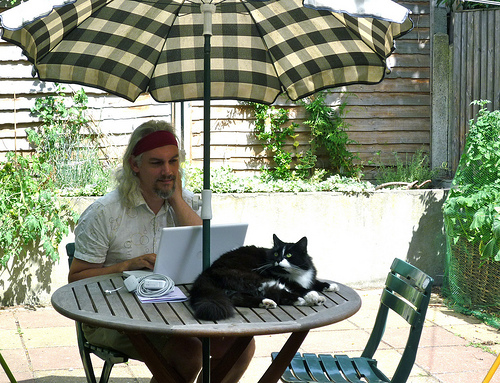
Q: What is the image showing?
A: It is showing a patio.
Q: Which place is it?
A: It is a patio.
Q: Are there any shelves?
A: No, there are no shelves.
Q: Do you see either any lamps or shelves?
A: No, there are no shelves or lamps.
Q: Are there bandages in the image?
A: No, there are no bandages.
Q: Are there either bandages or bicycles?
A: No, there are no bandages or bicycles.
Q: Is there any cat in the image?
A: Yes, there is a cat.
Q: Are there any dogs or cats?
A: Yes, there is a cat.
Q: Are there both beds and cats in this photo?
A: No, there is a cat but no beds.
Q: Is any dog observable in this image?
A: No, there are no dogs.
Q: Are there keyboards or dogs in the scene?
A: No, there are no dogs or keyboards.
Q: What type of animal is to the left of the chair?
A: The animal is a cat.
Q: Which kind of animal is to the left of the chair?
A: The animal is a cat.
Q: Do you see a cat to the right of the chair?
A: No, the cat is to the left of the chair.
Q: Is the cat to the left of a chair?
A: Yes, the cat is to the left of a chair.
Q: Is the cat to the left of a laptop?
A: No, the cat is to the left of a chair.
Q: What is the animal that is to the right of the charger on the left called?
A: The animal is a cat.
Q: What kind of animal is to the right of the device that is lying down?
A: The animal is a cat.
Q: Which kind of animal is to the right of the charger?
A: The animal is a cat.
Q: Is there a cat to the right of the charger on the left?
A: Yes, there is a cat to the right of the charger.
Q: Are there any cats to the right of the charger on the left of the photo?
A: Yes, there is a cat to the right of the charger.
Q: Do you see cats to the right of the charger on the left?
A: Yes, there is a cat to the right of the charger.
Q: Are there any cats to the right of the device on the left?
A: Yes, there is a cat to the right of the charger.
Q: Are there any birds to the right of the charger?
A: No, there is a cat to the right of the charger.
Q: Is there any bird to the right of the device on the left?
A: No, there is a cat to the right of the charger.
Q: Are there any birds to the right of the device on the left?
A: No, there is a cat to the right of the charger.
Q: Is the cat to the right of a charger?
A: Yes, the cat is to the right of a charger.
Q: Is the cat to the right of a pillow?
A: No, the cat is to the right of a charger.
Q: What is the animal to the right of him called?
A: The animal is a cat.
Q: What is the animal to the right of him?
A: The animal is a cat.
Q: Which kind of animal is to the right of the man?
A: The animal is a cat.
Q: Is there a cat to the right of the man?
A: Yes, there is a cat to the right of the man.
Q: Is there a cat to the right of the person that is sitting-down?
A: Yes, there is a cat to the right of the man.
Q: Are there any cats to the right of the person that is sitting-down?
A: Yes, there is a cat to the right of the man.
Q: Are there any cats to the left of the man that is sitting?
A: No, the cat is to the right of the man.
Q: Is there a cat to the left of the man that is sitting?
A: No, the cat is to the right of the man.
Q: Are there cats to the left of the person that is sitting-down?
A: No, the cat is to the right of the man.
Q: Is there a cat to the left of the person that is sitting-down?
A: No, the cat is to the right of the man.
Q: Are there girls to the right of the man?
A: No, there is a cat to the right of the man.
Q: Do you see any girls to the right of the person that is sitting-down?
A: No, there is a cat to the right of the man.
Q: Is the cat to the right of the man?
A: Yes, the cat is to the right of the man.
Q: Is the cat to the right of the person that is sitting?
A: Yes, the cat is to the right of the man.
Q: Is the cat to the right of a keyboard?
A: No, the cat is to the right of the man.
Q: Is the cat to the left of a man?
A: No, the cat is to the right of a man.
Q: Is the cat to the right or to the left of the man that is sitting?
A: The cat is to the right of the man.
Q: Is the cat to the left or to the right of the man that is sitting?
A: The cat is to the right of the man.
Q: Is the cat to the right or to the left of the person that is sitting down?
A: The cat is to the right of the man.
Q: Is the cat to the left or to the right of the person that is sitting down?
A: The cat is to the right of the man.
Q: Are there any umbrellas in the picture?
A: Yes, there is an umbrella.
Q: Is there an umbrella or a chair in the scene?
A: Yes, there is an umbrella.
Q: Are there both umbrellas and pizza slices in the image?
A: No, there is an umbrella but no pizza slices.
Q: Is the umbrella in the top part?
A: Yes, the umbrella is in the top of the image.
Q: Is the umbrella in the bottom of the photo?
A: No, the umbrella is in the top of the image.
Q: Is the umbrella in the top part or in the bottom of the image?
A: The umbrella is in the top of the image.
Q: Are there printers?
A: No, there are no printers.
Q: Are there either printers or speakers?
A: No, there are no printers or speakers.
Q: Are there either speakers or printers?
A: No, there are no printers or speakers.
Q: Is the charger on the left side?
A: Yes, the charger is on the left of the image.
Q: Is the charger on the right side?
A: No, the charger is on the left of the image.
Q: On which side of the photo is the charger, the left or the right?
A: The charger is on the left of the image.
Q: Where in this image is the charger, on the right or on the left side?
A: The charger is on the left of the image.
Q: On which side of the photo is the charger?
A: The charger is on the left of the image.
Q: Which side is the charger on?
A: The charger is on the left of the image.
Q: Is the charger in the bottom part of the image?
A: Yes, the charger is in the bottom of the image.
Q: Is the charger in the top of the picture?
A: No, the charger is in the bottom of the image.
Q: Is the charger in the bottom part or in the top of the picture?
A: The charger is in the bottom of the image.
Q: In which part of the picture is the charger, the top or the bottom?
A: The charger is in the bottom of the image.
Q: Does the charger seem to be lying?
A: Yes, the charger is lying.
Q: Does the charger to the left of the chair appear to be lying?
A: Yes, the charger is lying.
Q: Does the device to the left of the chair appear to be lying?
A: Yes, the charger is lying.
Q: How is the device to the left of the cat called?
A: The device is a charger.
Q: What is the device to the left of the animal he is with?
A: The device is a charger.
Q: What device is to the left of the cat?
A: The device is a charger.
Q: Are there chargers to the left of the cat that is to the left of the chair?
A: Yes, there is a charger to the left of the cat.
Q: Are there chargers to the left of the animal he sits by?
A: Yes, there is a charger to the left of the cat.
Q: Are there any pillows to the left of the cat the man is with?
A: No, there is a charger to the left of the cat.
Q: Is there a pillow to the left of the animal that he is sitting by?
A: No, there is a charger to the left of the cat.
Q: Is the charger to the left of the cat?
A: Yes, the charger is to the left of the cat.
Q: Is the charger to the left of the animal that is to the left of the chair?
A: Yes, the charger is to the left of the cat.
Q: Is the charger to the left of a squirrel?
A: No, the charger is to the left of the cat.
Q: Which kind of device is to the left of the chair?
A: The device is a charger.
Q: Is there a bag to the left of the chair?
A: No, there is a charger to the left of the chair.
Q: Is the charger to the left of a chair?
A: Yes, the charger is to the left of a chair.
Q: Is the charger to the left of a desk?
A: No, the charger is to the left of a chair.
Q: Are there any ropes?
A: No, there are no ropes.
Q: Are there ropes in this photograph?
A: No, there are no ropes.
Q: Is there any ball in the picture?
A: No, there are no balls.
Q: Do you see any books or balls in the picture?
A: No, there are no balls or books.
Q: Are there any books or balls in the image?
A: No, there are no balls or books.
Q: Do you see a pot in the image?
A: No, there are no pots.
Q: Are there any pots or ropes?
A: No, there are no pots or ropes.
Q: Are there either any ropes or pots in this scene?
A: No, there are no pots or ropes.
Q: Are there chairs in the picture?
A: Yes, there is a chair.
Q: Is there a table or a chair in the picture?
A: Yes, there is a chair.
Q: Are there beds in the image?
A: No, there are no beds.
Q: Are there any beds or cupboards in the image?
A: No, there are no beds or cupboards.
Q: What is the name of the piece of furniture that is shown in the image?
A: The piece of furniture is a chair.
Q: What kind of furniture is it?
A: The piece of furniture is a chair.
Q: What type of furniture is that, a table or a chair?
A: This is a chair.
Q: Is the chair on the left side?
A: No, the chair is on the right of the image.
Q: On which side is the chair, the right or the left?
A: The chair is on the right of the image.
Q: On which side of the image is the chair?
A: The chair is on the right of the image.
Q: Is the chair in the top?
A: No, the chair is in the bottom of the image.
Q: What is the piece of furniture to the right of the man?
A: The piece of furniture is a chair.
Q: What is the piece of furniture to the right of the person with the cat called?
A: The piece of furniture is a chair.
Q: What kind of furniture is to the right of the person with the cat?
A: The piece of furniture is a chair.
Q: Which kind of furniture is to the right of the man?
A: The piece of furniture is a chair.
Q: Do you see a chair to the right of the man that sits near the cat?
A: Yes, there is a chair to the right of the man.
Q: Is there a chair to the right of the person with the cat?
A: Yes, there is a chair to the right of the man.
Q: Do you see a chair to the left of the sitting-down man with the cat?
A: No, the chair is to the right of the man.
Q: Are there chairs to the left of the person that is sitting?
A: No, the chair is to the right of the man.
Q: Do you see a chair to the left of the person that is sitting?
A: No, the chair is to the right of the man.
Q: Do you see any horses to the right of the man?
A: No, there is a chair to the right of the man.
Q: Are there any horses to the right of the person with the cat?
A: No, there is a chair to the right of the man.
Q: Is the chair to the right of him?
A: Yes, the chair is to the right of the man.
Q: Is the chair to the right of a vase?
A: No, the chair is to the right of the man.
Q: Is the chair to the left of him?
A: No, the chair is to the right of a man.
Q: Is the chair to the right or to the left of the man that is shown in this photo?
A: The chair is to the right of the man.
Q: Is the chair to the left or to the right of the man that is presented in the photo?
A: The chair is to the right of the man.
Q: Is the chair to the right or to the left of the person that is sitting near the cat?
A: The chair is to the right of the man.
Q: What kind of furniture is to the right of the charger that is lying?
A: The piece of furniture is a chair.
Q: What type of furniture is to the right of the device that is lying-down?
A: The piece of furniture is a chair.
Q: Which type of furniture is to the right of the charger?
A: The piece of furniture is a chair.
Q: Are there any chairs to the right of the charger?
A: Yes, there is a chair to the right of the charger.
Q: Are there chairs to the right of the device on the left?
A: Yes, there is a chair to the right of the charger.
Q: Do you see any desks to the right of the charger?
A: No, there is a chair to the right of the charger.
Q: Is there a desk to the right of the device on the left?
A: No, there is a chair to the right of the charger.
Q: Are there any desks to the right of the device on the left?
A: No, there is a chair to the right of the charger.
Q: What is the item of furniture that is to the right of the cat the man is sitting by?
A: The piece of furniture is a chair.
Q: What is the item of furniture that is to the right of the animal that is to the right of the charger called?
A: The piece of furniture is a chair.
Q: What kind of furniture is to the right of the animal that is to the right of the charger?
A: The piece of furniture is a chair.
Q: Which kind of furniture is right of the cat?
A: The piece of furniture is a chair.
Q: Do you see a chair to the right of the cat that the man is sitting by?
A: Yes, there is a chair to the right of the cat.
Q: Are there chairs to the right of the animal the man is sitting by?
A: Yes, there is a chair to the right of the cat.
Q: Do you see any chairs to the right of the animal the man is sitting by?
A: Yes, there is a chair to the right of the cat.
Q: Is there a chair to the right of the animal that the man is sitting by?
A: Yes, there is a chair to the right of the cat.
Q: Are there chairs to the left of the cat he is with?
A: No, the chair is to the right of the cat.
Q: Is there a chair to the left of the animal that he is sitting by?
A: No, the chair is to the right of the cat.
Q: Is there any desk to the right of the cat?
A: No, there is a chair to the right of the cat.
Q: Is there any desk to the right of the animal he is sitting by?
A: No, there is a chair to the right of the cat.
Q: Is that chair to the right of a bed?
A: No, the chair is to the right of a cat.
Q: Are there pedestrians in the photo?
A: No, there are no pedestrians.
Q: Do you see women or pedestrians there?
A: No, there are no pedestrians or women.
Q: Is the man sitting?
A: Yes, the man is sitting.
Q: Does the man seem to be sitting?
A: Yes, the man is sitting.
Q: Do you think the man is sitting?
A: Yes, the man is sitting.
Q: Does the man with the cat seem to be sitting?
A: Yes, the man is sitting.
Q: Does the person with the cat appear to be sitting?
A: Yes, the man is sitting.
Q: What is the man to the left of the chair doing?
A: The man is sitting.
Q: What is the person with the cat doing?
A: The man is sitting.